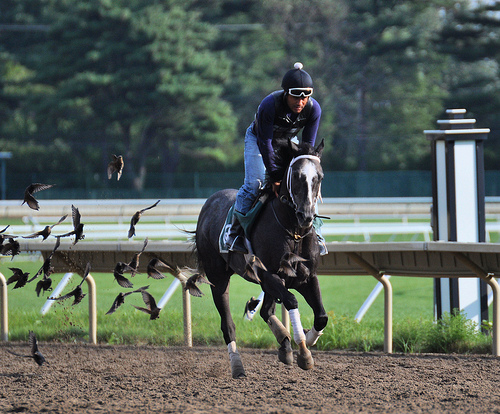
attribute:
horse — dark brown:
[191, 139, 330, 379]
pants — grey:
[227, 112, 279, 252]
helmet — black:
[239, 55, 340, 121]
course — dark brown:
[55, 277, 492, 392]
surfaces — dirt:
[79, 355, 210, 399]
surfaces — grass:
[339, 314, 379, 344]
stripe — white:
[300, 159, 319, 206]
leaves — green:
[0, 0, 498, 158]